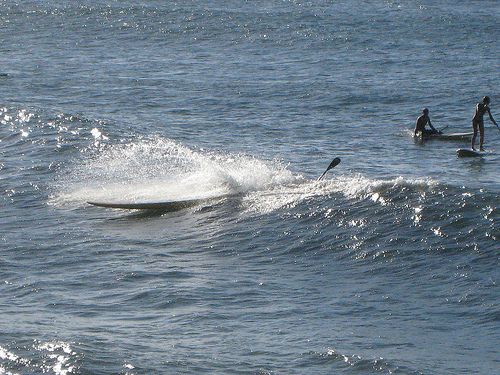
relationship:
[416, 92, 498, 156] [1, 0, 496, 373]
people on water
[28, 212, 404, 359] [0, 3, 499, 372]
ripples in ocean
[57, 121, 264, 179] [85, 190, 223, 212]
splash over surfboard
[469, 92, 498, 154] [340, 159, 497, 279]
person standing on water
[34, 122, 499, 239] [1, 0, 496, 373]
wave in water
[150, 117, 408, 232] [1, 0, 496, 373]
wave in water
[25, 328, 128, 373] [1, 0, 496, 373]
wave in water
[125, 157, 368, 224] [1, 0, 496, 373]
wave in water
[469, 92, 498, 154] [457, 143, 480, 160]
person standing on a surfboard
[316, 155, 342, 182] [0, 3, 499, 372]
paddle sticking out of ocean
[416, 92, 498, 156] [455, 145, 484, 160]
people standing on surfboard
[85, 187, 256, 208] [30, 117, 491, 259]
surfboard in a wave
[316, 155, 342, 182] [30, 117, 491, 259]
paddle in a wave